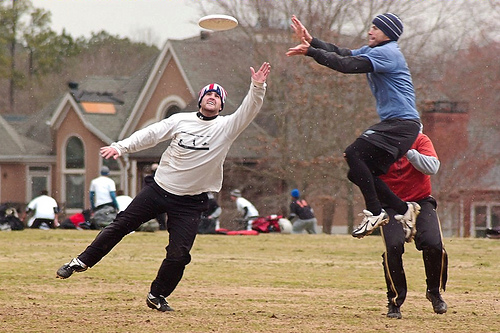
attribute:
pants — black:
[94, 242, 181, 311]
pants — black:
[62, 175, 212, 332]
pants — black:
[85, 274, 215, 304]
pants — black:
[62, 186, 232, 331]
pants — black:
[110, 211, 192, 313]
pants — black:
[99, 187, 183, 285]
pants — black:
[88, 235, 202, 318]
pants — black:
[103, 226, 186, 285]